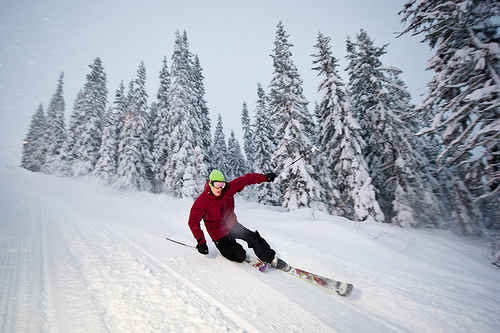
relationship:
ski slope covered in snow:
[12, 169, 387, 317] [2, 163, 499, 331]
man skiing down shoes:
[186, 168, 286, 270] [257, 257, 288, 269]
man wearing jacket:
[186, 169, 285, 270] [187, 172, 265, 244]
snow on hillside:
[2, 163, 499, 331] [0, 164, 500, 329]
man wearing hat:
[186, 169, 285, 270] [204, 165, 231, 182]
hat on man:
[209, 170, 226, 178] [188, 170, 290, 260]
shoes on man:
[243, 253, 289, 270] [184, 166, 289, 278]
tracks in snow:
[6, 167, 246, 332] [2, 163, 499, 331]